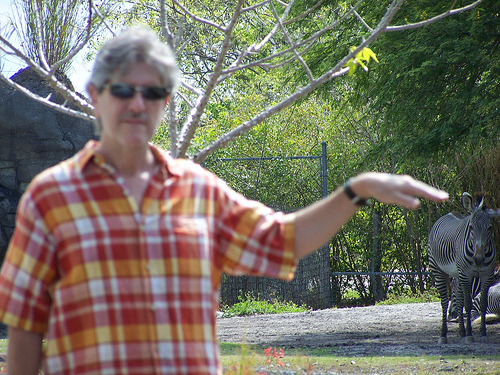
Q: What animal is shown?
A: Zebra.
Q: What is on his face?
A: Sunglasses.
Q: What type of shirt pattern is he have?
A: Plaid.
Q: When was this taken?
A: Daytime.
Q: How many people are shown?
A: 1.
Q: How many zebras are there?
A: 2.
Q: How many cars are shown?
A: 0.